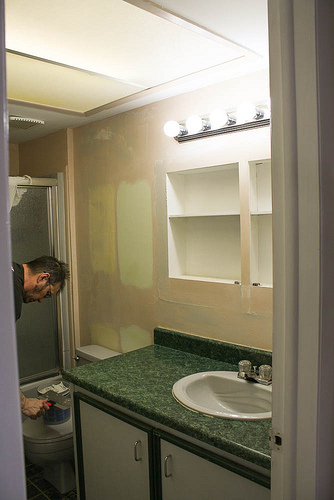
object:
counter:
[62, 329, 272, 470]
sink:
[173, 371, 272, 419]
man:
[12, 256, 70, 420]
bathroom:
[4, 0, 270, 499]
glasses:
[43, 270, 53, 301]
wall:
[71, 70, 272, 352]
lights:
[163, 116, 181, 142]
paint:
[39, 380, 71, 426]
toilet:
[23, 345, 122, 493]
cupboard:
[78, 401, 270, 500]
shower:
[7, 143, 70, 388]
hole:
[273, 434, 282, 447]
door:
[269, 1, 294, 499]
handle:
[132, 439, 142, 462]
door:
[77, 401, 151, 500]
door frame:
[269, 2, 320, 500]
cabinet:
[165, 159, 275, 287]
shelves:
[167, 208, 239, 228]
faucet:
[237, 370, 256, 383]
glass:
[8, 188, 61, 386]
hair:
[25, 256, 70, 293]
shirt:
[13, 263, 24, 321]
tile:
[28, 466, 76, 500]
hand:
[19, 396, 49, 420]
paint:
[87, 179, 153, 354]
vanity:
[64, 325, 271, 499]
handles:
[162, 454, 171, 478]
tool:
[45, 399, 56, 409]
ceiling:
[6, 1, 270, 146]